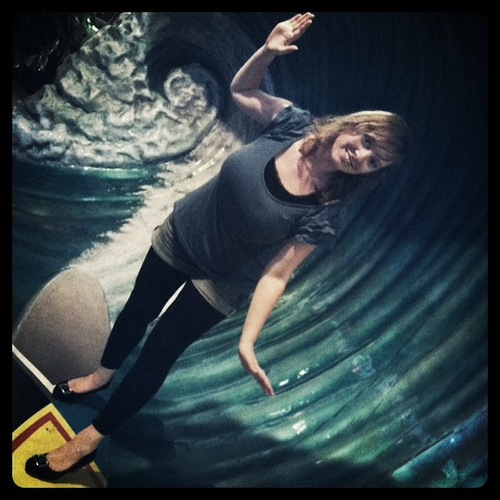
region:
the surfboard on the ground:
[10, 266, 110, 497]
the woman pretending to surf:
[26, 10, 413, 499]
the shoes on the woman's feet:
[25, 369, 115, 481]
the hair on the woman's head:
[299, 109, 410, 204]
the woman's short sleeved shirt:
[173, 101, 345, 311]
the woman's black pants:
[89, 239, 227, 438]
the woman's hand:
[266, 10, 316, 51]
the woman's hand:
[238, 345, 273, 396]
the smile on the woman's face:
[343, 146, 355, 171]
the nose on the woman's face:
[354, 148, 371, 164]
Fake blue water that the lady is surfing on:
[295, 395, 348, 437]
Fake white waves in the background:
[88, 97, 146, 144]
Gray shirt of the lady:
[216, 193, 253, 253]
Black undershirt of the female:
[267, 170, 277, 186]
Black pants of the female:
[126, 298, 182, 366]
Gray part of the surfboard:
[63, 304, 88, 328]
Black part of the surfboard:
[13, 387, 28, 401]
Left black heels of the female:
[32, 459, 42, 471]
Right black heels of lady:
[58, 383, 67, 396]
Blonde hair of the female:
[379, 118, 399, 135]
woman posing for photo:
[0, 39, 432, 485]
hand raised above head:
[225, 8, 429, 202]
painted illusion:
[13, 10, 488, 491]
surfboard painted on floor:
[0, 248, 143, 494]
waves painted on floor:
[9, 17, 495, 472]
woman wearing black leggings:
[26, 79, 412, 473]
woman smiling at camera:
[326, 95, 428, 212]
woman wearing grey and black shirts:
[141, 8, 454, 447]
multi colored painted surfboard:
[9, 239, 109, 494]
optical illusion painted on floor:
[13, 12, 483, 490]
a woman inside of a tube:
[14, 13, 458, 483]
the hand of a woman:
[236, 344, 276, 399]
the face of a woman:
[332, 133, 382, 172]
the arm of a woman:
[231, 233, 318, 398]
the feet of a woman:
[23, 356, 113, 486]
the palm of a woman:
[258, 19, 295, 49]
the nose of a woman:
[353, 148, 364, 164]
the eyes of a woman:
[358, 130, 383, 170]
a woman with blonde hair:
[297, 117, 427, 197]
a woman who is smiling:
[321, 100, 409, 198]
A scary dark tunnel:
[13, 21, 202, 181]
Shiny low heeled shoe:
[26, 453, 56, 476]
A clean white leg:
[55, 428, 98, 467]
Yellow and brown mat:
[13, 406, 60, 443]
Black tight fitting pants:
[116, 302, 178, 390]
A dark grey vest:
[194, 185, 267, 259]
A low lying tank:
[316, 340, 481, 466]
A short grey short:
[150, 225, 171, 258]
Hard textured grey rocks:
[50, 67, 190, 147]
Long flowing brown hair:
[301, 120, 326, 180]